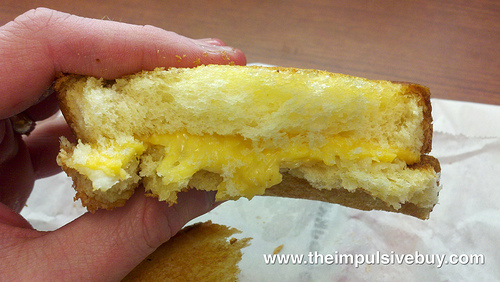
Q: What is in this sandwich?
A: Cheese.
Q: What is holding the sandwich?
A: Fingers.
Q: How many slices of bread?
A: 2.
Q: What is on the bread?
A: Butter.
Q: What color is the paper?
A: White.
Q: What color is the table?
A: Brown.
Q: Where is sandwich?
A: In fingers.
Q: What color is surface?
A: White.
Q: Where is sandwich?
A: In hand.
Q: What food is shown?
A: Sandwich.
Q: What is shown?
A: Sandwich.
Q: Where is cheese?
A: On sandwich.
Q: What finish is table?
A: Wooden.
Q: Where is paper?
A: Under sandwich.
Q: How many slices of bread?
A: Two.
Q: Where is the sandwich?
A: In the person's hand.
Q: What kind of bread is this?
A: Toasted.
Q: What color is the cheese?
A: Yellow.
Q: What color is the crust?
A: Brown.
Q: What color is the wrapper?
A: White.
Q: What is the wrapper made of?
A: Paper.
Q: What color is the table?
A: Brown.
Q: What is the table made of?
A: Wood.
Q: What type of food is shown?
A: Sandwich.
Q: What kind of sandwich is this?
A: Grilled cheese.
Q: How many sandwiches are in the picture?
A: 1.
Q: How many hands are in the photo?
A: 1.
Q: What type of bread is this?
A: White.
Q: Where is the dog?
A: No dog is present.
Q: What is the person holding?
A: A sandwhich.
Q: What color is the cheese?
A: Yellow.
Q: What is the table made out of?
A: Wood.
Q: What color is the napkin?
A: White.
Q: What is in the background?
A: A napkin.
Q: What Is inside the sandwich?
A: Cheese.